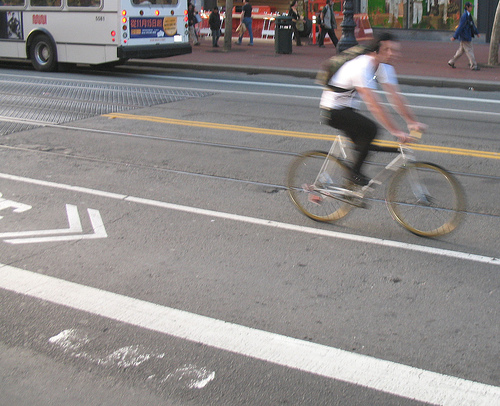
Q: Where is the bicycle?
A: On the road.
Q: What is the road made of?
A: Asphalt.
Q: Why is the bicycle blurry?
A: It is in motion.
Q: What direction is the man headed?
A: Right.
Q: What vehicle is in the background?
A: Bus.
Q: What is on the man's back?
A: Backpack.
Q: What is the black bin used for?
A: Garbage.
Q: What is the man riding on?
A: Bicycle.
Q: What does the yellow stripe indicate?
A: Lanes.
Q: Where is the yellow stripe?
A: On the road.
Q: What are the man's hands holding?
A: Handlebars.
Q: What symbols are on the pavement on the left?
A: Arrows.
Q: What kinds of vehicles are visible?
A: Bus and bicycle.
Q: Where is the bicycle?
A: Next to the bike lane.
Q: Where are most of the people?
A: On the sidewalk.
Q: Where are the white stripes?
A: On the road.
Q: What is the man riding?
A: A bike.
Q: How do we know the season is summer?
A: The biker is wearing short sleeves.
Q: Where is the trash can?
A: Next to the construction site.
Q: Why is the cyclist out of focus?
A: He is moving.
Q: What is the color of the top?
A: White.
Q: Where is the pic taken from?
A: On a street.